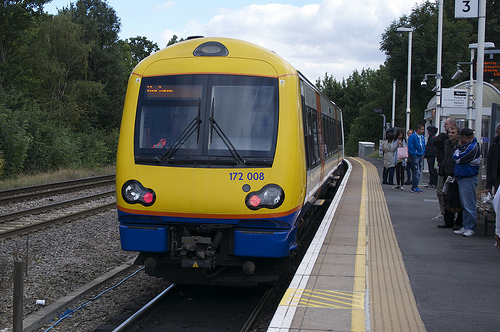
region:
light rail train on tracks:
[127, 37, 357, 233]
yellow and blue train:
[136, 27, 328, 239]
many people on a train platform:
[375, 120, 482, 205]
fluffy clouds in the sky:
[193, 6, 384, 52]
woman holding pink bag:
[392, 130, 410, 165]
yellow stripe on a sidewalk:
[342, 154, 375, 329]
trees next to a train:
[16, 15, 344, 239]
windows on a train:
[146, 55, 292, 175]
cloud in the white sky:
[133, 3, 390, 40]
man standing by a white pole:
[453, 3, 488, 234]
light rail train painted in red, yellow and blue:
[114, 35, 344, 257]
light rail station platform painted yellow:
[341, 146, 402, 329]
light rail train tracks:
[14, 174, 114, 316]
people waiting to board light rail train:
[376, 109, 490, 237]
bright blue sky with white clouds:
[186, 0, 402, 35]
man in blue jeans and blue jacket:
[405, 118, 426, 197]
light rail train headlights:
[122, 168, 293, 210]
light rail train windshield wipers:
[165, 104, 246, 164]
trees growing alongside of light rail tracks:
[11, 11, 103, 163]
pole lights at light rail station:
[382, 18, 494, 140]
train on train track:
[94, 14, 353, 309]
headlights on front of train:
[115, 164, 304, 213]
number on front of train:
[222, 165, 271, 183]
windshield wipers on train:
[150, 106, 259, 168]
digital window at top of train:
[137, 74, 204, 106]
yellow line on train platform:
[347, 154, 375, 331]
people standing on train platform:
[371, 116, 493, 246]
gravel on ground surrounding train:
[7, 168, 170, 330]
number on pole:
[447, 2, 494, 136]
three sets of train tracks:
[7, 165, 276, 323]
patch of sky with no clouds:
[130, 15, 187, 25]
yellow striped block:
[286, 285, 357, 306]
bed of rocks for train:
[30, 232, 85, 272]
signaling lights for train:
[115, 175, 286, 206]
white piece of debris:
[35, 296, 51, 303]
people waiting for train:
[380, 116, 477, 233]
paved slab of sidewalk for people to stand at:
[416, 240, 474, 290]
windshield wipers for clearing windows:
[162, 115, 243, 161]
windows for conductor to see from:
[138, 73, 271, 165]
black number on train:
[227, 168, 235, 182]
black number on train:
[236, 169, 243, 183]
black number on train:
[251, 170, 260, 182]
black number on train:
[257, 169, 265, 183]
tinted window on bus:
[210, 75, 275, 161]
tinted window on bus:
[313, 108, 319, 162]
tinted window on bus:
[323, 113, 330, 155]